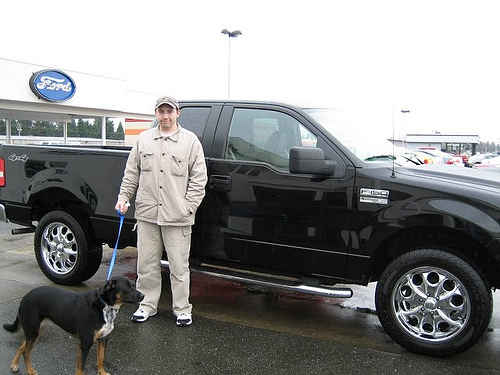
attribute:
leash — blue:
[98, 209, 121, 287]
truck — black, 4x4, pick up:
[0, 98, 492, 356]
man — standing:
[115, 98, 209, 329]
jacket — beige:
[117, 124, 210, 224]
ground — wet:
[213, 296, 433, 373]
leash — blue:
[104, 210, 134, 276]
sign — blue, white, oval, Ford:
[24, 68, 76, 108]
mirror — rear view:
[286, 146, 327, 176]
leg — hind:
[8, 334, 29, 373]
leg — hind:
[26, 331, 34, 368]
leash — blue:
[104, 212, 126, 278]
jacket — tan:
[118, 125, 208, 231]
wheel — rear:
[30, 205, 105, 283]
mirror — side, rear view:
[285, 144, 345, 184]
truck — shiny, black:
[11, 83, 483, 363]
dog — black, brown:
[6, 271, 146, 367]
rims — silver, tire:
[389, 260, 473, 341]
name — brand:
[26, 64, 77, 104]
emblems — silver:
[355, 180, 393, 211]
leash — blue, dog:
[103, 216, 125, 283]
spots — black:
[104, 304, 120, 324]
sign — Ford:
[22, 64, 84, 106]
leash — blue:
[106, 204, 125, 281]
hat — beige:
[154, 95, 178, 108]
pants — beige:
[134, 227, 192, 314]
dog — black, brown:
[3, 272, 144, 373]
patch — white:
[97, 302, 121, 342]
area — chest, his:
[94, 303, 122, 338]